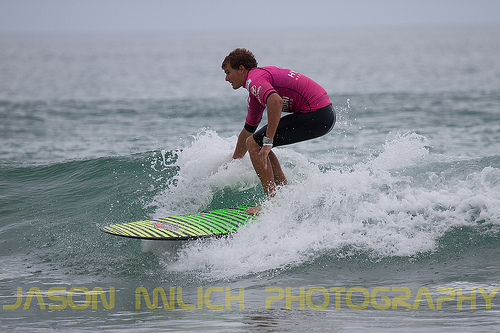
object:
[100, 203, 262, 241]
surfboard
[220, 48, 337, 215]
man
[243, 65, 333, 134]
shirt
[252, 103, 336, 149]
swimming shorts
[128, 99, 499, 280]
wave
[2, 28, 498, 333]
water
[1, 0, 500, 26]
sky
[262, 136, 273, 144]
watch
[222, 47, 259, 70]
hair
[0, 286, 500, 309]
watermark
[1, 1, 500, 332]
picture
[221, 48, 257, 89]
head